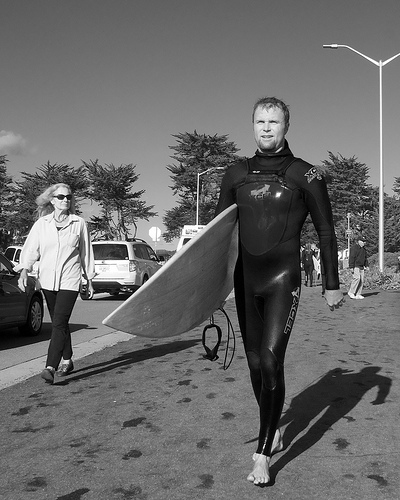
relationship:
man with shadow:
[227, 88, 364, 495] [275, 352, 386, 472]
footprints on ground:
[8, 305, 389, 500] [123, 429, 216, 486]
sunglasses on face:
[49, 191, 74, 202] [43, 182, 72, 214]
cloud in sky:
[0, 130, 37, 158] [94, 42, 182, 119]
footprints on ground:
[12, 303, 387, 496] [0, 289, 400, 500]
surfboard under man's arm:
[104, 200, 240, 336] [214, 160, 237, 216]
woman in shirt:
[13, 183, 101, 383] [18, 212, 96, 289]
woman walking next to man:
[13, 183, 101, 383] [212, 96, 346, 487]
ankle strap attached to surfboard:
[201, 307, 235, 371] [104, 200, 240, 336]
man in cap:
[345, 236, 370, 299] [356, 234, 369, 243]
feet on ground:
[249, 431, 281, 487] [0, 289, 400, 500]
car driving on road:
[80, 238, 165, 301] [0, 291, 133, 369]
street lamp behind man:
[194, 165, 223, 221] [212, 96, 346, 487]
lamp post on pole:
[322, 43, 400, 272] [377, 58, 385, 274]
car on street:
[82, 237, 166, 300] [0, 295, 135, 371]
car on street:
[0, 252, 45, 342] [0, 295, 135, 371]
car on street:
[6, 245, 39, 285] [1, 292, 132, 368]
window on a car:
[90, 244, 127, 260] [87, 236, 163, 297]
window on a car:
[134, 242, 150, 256] [81, 239, 163, 302]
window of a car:
[6, 247, 13, 258] [5, 244, 41, 277]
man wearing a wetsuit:
[212, 96, 346, 487] [216, 141, 339, 458]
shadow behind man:
[260, 365, 392, 489] [212, 96, 346, 487]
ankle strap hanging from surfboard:
[202, 308, 236, 370] [104, 200, 240, 336]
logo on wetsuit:
[281, 286, 300, 335] [216, 141, 339, 458]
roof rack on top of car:
[94, 236, 144, 244] [80, 238, 165, 301]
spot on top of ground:
[196, 473, 213, 491] [0, 289, 400, 500]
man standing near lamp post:
[348, 237, 368, 300] [323, 42, 398, 276]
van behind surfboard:
[177, 223, 209, 255] [104, 200, 240, 336]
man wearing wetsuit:
[212, 96, 346, 487] [216, 141, 339, 458]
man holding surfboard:
[212, 96, 346, 487] [104, 200, 240, 336]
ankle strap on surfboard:
[202, 308, 236, 370] [104, 200, 240, 336]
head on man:
[251, 94, 290, 152] [212, 96, 346, 487]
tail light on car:
[127, 259, 138, 272] [82, 237, 166, 300]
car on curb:
[80, 238, 165, 301] [0, 326, 136, 389]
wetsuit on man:
[216, 141, 339, 458] [212, 96, 346, 487]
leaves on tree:
[167, 128, 233, 179] [169, 128, 242, 224]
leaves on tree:
[97, 173, 144, 202] [90, 160, 159, 242]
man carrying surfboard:
[212, 96, 346, 487] [104, 200, 240, 336]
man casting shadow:
[212, 96, 346, 487] [260, 365, 392, 489]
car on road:
[80, 238, 165, 301] [0, 288, 136, 375]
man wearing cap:
[348, 237, 368, 300] [358, 236, 367, 242]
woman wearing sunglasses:
[12, 183, 99, 384] [49, 191, 73, 201]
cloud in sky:
[0, 127, 38, 158] [1, 0, 398, 248]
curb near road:
[0, 329, 133, 388] [0, 291, 133, 369]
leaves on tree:
[319, 148, 369, 188] [314, 151, 370, 248]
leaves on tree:
[364, 218, 377, 236] [356, 202, 398, 256]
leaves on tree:
[21, 160, 90, 201] [14, 159, 92, 239]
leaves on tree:
[14, 206, 31, 223] [11, 179, 41, 245]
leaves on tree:
[119, 201, 158, 221] [116, 198, 158, 244]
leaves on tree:
[164, 207, 178, 230] [162, 198, 209, 242]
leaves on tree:
[159, 207, 179, 230] [160, 203, 198, 241]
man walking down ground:
[212, 96, 346, 487] [0, 289, 400, 500]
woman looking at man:
[13, 183, 101, 383] [212, 96, 346, 487]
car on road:
[2, 245, 40, 279] [88, 304, 96, 319]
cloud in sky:
[0, 130, 37, 158] [47, 7, 327, 92]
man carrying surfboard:
[212, 96, 346, 487] [92, 210, 239, 351]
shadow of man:
[291, 357, 386, 469] [180, 95, 366, 493]